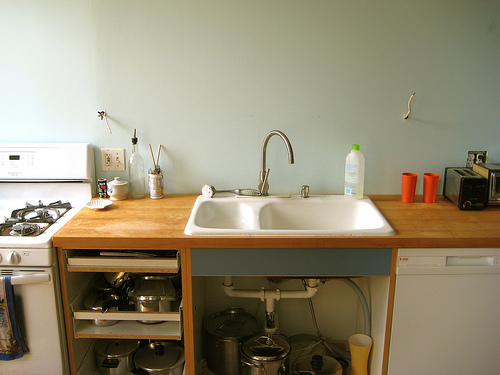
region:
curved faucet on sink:
[255, 127, 297, 198]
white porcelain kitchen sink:
[180, 187, 395, 244]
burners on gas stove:
[4, 193, 59, 243]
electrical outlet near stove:
[96, 147, 126, 174]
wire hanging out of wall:
[398, 85, 420, 122]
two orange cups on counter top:
[398, 165, 450, 207]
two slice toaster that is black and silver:
[442, 162, 485, 209]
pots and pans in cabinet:
[81, 276, 192, 342]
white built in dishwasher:
[389, 247, 499, 372]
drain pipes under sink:
[217, 278, 326, 328]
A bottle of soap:
[344, 143, 366, 198]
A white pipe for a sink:
[220, 276, 319, 335]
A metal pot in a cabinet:
[93, 338, 138, 373]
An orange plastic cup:
[399, 172, 417, 202]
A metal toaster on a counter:
[442, 166, 489, 210]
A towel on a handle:
[1, 276, 28, 360]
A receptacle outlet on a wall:
[100, 147, 126, 172]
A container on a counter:
[145, 140, 164, 198]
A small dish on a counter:
[86, 199, 113, 209]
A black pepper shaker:
[95, 177, 107, 199]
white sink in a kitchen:
[183, 186, 398, 258]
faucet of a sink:
[245, 126, 300, 198]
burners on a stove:
[11, 194, 68, 239]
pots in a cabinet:
[71, 281, 173, 332]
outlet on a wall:
[95, 142, 129, 174]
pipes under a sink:
[219, 281, 324, 316]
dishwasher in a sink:
[394, 241, 498, 364]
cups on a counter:
[397, 167, 440, 207]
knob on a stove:
[4, 247, 24, 269]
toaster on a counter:
[437, 157, 494, 219]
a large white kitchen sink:
[182, 191, 391, 238]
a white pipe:
[222, 275, 319, 312]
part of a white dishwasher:
[387, 247, 497, 374]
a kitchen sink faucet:
[230, 125, 296, 199]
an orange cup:
[401, 171, 418, 203]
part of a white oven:
[0, 142, 97, 374]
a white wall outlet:
[100, 146, 127, 173]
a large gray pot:
[205, 305, 257, 373]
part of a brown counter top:
[370, 190, 498, 242]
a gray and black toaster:
[444, 164, 490, 210]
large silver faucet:
[261, 127, 296, 191]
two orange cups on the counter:
[397, 167, 441, 208]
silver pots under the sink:
[206, 300, 289, 373]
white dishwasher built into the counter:
[383, 245, 499, 373]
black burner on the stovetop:
[15, 198, 68, 223]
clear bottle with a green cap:
[340, 141, 370, 197]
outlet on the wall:
[98, 147, 128, 174]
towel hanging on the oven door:
[0, 275, 30, 361]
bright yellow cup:
[348, 331, 380, 373]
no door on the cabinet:
[58, 245, 187, 373]